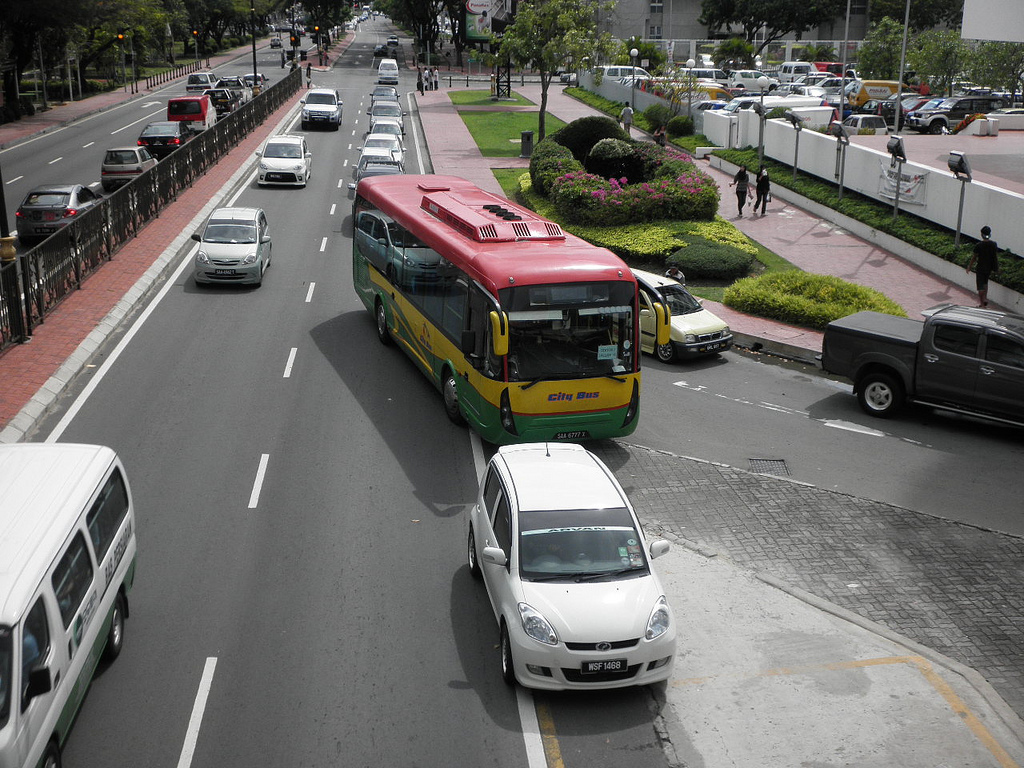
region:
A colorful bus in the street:
[346, 166, 670, 441]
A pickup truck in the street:
[814, 291, 1012, 431]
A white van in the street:
[1, 443, 129, 761]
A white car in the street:
[459, 437, 674, 697]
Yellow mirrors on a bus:
[485, 303, 512, 361]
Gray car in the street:
[193, 196, 271, 296]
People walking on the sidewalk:
[731, 157, 779, 218]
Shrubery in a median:
[525, 108, 639, 182]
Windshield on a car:
[513, 506, 653, 584]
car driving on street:
[18, 178, 108, 243]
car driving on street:
[135, 114, 198, 159]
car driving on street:
[165, 89, 221, 145]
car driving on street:
[189, 204, 274, 289]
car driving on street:
[252, 134, 312, 190]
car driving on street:
[297, 78, 344, 132]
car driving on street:
[468, 438, 672, 694]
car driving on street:
[615, 256, 734, 370]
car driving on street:
[363, 130, 405, 163]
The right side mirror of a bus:
[490, 313, 507, 356]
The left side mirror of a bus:
[655, 301, 668, 340]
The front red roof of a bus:
[501, 243, 586, 276]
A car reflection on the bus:
[364, 213, 391, 246]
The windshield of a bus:
[530, 328, 588, 372]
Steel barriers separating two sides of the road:
[46, 245, 85, 284]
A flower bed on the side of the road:
[608, 186, 687, 226]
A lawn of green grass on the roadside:
[475, 112, 535, 129]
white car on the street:
[443, 417, 693, 719]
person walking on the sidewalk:
[957, 208, 1003, 311]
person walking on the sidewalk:
[727, 160, 756, 227]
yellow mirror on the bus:
[483, 306, 510, 363]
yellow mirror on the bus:
[644, 294, 683, 359]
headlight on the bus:
[493, 380, 532, 439]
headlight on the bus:
[622, 377, 643, 423]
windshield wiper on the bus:
[515, 350, 640, 414]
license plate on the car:
[580, 654, 632, 675]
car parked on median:
[455, 437, 693, 704]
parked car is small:
[441, 434, 677, 697]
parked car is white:
[446, 431, 685, 707]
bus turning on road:
[333, 160, 654, 459]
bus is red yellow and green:
[345, 153, 658, 460]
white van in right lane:
[4, 437, 157, 767]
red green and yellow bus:
[349, 174, 635, 443]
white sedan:
[464, 440, 673, 688]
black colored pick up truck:
[805, 304, 1021, 416]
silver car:
[192, 207, 269, 284]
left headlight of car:
[514, 602, 557, 644]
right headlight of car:
[643, 589, 673, 640]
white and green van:
[0, 441, 134, 761]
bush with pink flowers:
[551, 138, 720, 216]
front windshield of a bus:
[498, 302, 639, 378]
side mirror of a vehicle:
[480, 544, 512, 570]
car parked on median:
[453, 448, 678, 698]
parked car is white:
[444, 430, 682, 697]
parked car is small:
[444, 428, 673, 705]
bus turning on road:
[335, 156, 665, 451]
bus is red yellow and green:
[345, 164, 653, 458]